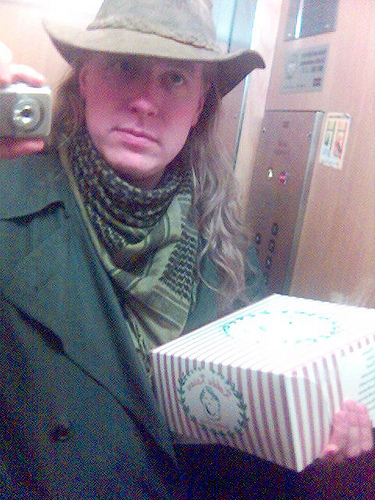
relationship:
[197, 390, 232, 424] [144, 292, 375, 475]
person on box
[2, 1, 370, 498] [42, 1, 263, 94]
man wearing a hat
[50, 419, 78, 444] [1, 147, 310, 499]
button on jacket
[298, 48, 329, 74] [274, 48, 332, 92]
writing on plaque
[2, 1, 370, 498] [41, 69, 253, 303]
man has hair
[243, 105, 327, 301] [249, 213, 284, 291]
panel filled with buttons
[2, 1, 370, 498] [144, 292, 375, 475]
man holding box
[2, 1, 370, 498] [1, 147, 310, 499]
man wearing a jacket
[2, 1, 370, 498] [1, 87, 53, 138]
man holding camera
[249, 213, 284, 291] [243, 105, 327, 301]
buttons on panel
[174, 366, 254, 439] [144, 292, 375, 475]
emblem on side of box